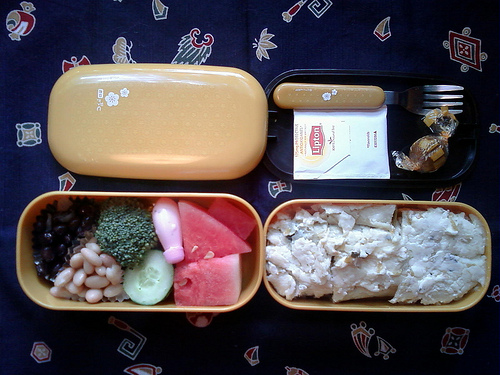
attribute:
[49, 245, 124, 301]
beans — beige, light pink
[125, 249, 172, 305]
cucumber — sliced, green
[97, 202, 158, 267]
broccoli — green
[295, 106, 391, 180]
envelope — white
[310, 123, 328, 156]
label — red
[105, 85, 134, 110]
flowers — white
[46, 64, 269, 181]
cover — plastic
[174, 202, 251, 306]
watermelon — diced, red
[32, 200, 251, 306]
meal — healthy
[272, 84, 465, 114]
fork — small, metal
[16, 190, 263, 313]
container — plastic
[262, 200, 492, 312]
container — plastic